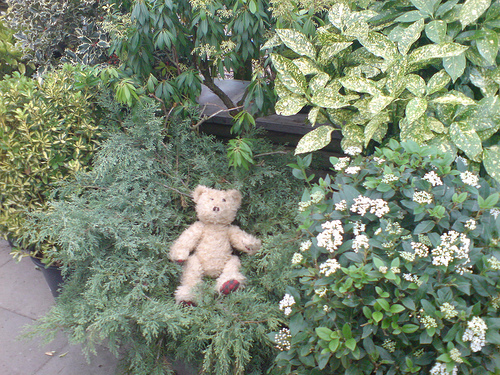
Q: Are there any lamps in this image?
A: No, there are no lamps.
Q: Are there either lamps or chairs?
A: No, there are no lamps or chairs.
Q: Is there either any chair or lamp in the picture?
A: No, there are no lamps or chairs.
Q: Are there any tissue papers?
A: No, there are no tissue papers.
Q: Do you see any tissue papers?
A: No, there are no tissue papers.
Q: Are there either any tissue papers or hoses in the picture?
A: No, there are no tissue papers or hoses.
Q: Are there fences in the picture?
A: No, there are no fences.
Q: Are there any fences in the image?
A: No, there are no fences.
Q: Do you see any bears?
A: Yes, there is a bear.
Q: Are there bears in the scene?
A: Yes, there is a bear.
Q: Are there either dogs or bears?
A: Yes, there is a bear.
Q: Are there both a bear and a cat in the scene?
A: No, there is a bear but no cats.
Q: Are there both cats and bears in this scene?
A: No, there is a bear but no cats.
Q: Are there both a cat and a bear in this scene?
A: No, there is a bear but no cats.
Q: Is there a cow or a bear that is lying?
A: Yes, the bear is lying.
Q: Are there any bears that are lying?
A: Yes, there is a bear that is lying.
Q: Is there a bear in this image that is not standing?
A: Yes, there is a bear that is lying.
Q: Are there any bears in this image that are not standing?
A: Yes, there is a bear that is lying.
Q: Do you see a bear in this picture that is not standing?
A: Yes, there is a bear that is lying .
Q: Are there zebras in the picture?
A: No, there are no zebras.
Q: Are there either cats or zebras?
A: No, there are no zebras or cats.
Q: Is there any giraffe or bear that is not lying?
A: No, there is a bear but it is lying.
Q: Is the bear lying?
A: Yes, the bear is lying.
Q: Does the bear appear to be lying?
A: Yes, the bear is lying.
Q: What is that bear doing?
A: The bear is lying.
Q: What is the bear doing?
A: The bear is lying.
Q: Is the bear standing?
A: No, the bear is lying.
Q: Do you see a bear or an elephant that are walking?
A: No, there is a bear but it is lying.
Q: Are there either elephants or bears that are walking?
A: No, there is a bear but it is lying.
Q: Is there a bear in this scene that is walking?
A: No, there is a bear but it is lying.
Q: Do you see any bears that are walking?
A: No, there is a bear but it is lying.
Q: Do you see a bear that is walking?
A: No, there is a bear but it is lying.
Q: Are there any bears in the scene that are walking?
A: No, there is a bear but it is lying.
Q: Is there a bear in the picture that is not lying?
A: No, there is a bear but it is lying.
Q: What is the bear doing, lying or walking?
A: The bear is lying.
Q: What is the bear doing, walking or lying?
A: The bear is lying.